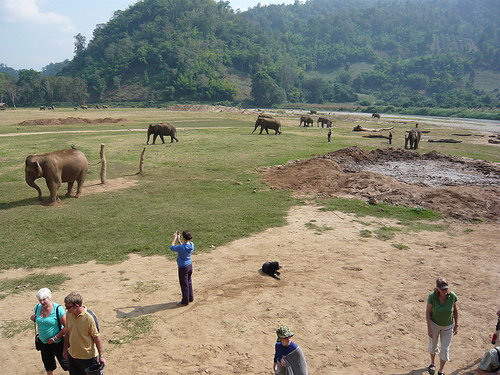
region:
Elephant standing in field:
[17, 144, 97, 204]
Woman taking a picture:
[170, 227, 209, 317]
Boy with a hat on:
[270, 314, 297, 372]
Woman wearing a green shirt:
[422, 256, 450, 373]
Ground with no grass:
[263, 203, 353, 257]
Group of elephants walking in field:
[240, 100, 372, 134]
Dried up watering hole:
[352, 140, 484, 206]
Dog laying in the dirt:
[244, 247, 305, 307]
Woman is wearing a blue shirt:
[167, 239, 204, 268]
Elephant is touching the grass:
[129, 110, 219, 155]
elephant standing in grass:
[15, 67, 400, 289]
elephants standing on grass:
[12, 93, 170, 256]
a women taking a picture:
[117, 191, 249, 373]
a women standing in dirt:
[139, 195, 217, 357]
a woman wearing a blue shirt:
[128, 170, 233, 310]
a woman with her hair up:
[133, 215, 265, 338]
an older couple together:
[23, 260, 146, 371]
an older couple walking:
[14, 241, 147, 373]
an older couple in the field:
[10, 257, 150, 372]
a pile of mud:
[266, 81, 497, 285]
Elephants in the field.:
[1, 92, 428, 209]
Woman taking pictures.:
[168, 223, 203, 305]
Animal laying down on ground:
[258, 258, 284, 283]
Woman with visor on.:
[425, 276, 460, 374]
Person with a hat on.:
[265, 323, 310, 373]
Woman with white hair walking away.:
[26, 283, 67, 373]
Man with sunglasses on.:
[52, 293, 109, 372]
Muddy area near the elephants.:
[261, 128, 497, 224]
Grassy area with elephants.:
[2, 106, 498, 348]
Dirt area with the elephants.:
[5, 206, 499, 371]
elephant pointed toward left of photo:
[12, 138, 90, 215]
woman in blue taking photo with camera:
[167, 223, 198, 257]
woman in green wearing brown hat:
[421, 277, 476, 334]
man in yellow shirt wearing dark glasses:
[59, 289, 101, 354]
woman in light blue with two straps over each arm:
[28, 289, 63, 364]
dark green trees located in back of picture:
[123, 5, 231, 80]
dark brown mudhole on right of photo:
[340, 155, 482, 222]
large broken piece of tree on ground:
[351, 118, 403, 135]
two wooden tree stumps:
[87, 141, 166, 204]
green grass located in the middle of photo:
[176, 186, 258, 233]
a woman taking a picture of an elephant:
[167, 221, 198, 312]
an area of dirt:
[295, 246, 391, 342]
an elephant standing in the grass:
[20, 145, 90, 205]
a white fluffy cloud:
[10, 0, 65, 30]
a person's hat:
[275, 325, 295, 337]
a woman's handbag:
[32, 335, 37, 345]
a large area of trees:
[112, 0, 488, 85]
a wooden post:
[135, 145, 145, 171]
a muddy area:
[375, 165, 490, 180]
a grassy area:
[89, 187, 246, 228]